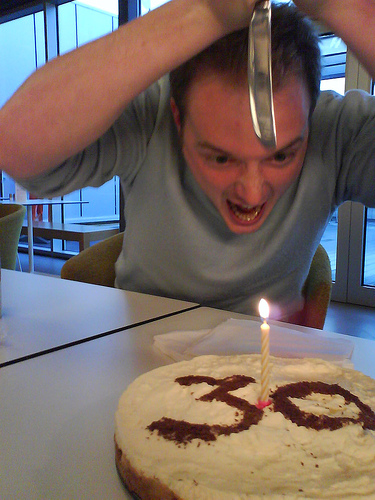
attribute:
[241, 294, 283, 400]
candle — lit, yellow, white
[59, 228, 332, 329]
chair — green, upholstered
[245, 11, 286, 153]
knife — silver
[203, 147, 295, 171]
eyes — open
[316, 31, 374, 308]
door — glass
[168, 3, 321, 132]
hair — short, brown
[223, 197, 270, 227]
mouth — open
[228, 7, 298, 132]
knife — cake knife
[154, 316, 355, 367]
napkin — white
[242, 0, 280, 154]
knife — silver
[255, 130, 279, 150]
tip — rounded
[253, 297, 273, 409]
candle — lit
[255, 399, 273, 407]
piece — pink, plastic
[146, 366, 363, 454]
number — 30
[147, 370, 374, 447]
number — 30